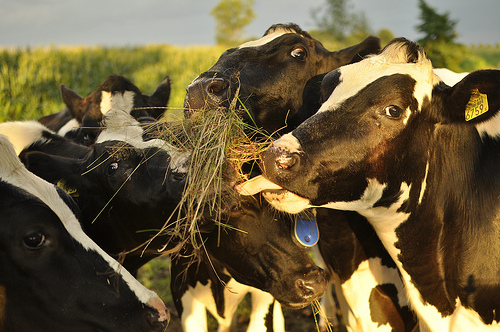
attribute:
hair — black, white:
[390, 31, 425, 65]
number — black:
[465, 101, 487, 117]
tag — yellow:
[460, 85, 495, 123]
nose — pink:
[269, 147, 302, 174]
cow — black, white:
[264, 46, 453, 253]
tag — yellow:
[440, 57, 495, 128]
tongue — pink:
[235, 166, 276, 198]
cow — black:
[263, 36, 499, 329]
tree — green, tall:
[412, 0, 464, 47]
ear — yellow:
[448, 67, 496, 127]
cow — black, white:
[184, 22, 379, 176]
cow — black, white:
[234, 37, 498, 329]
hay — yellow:
[138, 81, 273, 275]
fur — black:
[317, 130, 457, 166]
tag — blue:
[290, 208, 320, 251]